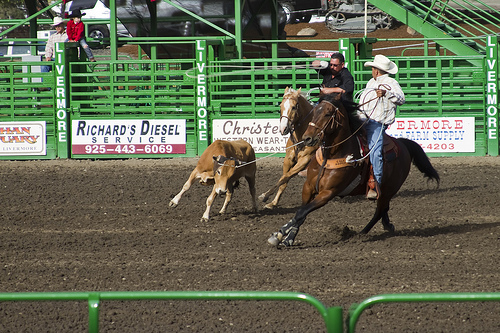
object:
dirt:
[0, 154, 500, 333]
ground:
[0, 155, 500, 333]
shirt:
[354, 74, 406, 128]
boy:
[62, 9, 97, 63]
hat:
[361, 53, 396, 75]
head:
[210, 153, 248, 198]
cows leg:
[170, 165, 201, 205]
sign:
[71, 118, 188, 154]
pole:
[484, 31, 500, 158]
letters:
[198, 130, 206, 142]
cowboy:
[356, 53, 405, 200]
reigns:
[321, 84, 392, 149]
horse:
[265, 87, 440, 247]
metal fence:
[0, 290, 500, 333]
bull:
[167, 139, 259, 223]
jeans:
[360, 118, 389, 187]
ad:
[70, 119, 186, 154]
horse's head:
[278, 86, 301, 136]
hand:
[373, 88, 386, 98]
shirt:
[62, 17, 85, 39]